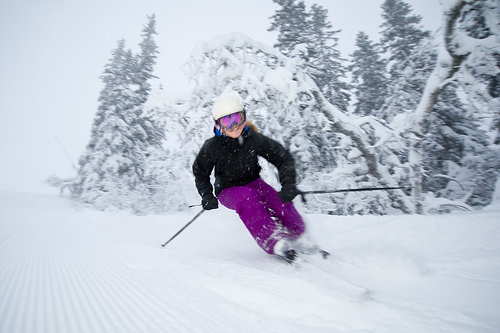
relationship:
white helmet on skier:
[204, 89, 255, 123] [193, 112, 303, 259]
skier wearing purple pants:
[192, 128, 305, 258] [215, 180, 306, 269]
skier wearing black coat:
[192, 128, 305, 258] [167, 121, 307, 213]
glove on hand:
[277, 180, 305, 209] [279, 188, 298, 200]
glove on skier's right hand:
[202, 193, 221, 209] [187, 179, 220, 216]